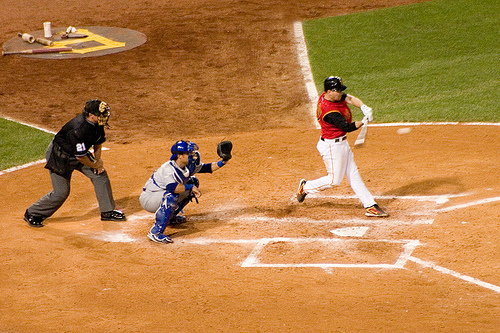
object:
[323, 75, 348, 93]
headgear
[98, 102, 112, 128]
mask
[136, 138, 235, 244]
catcher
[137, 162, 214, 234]
uniform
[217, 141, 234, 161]
mitt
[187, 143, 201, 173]
mask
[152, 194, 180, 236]
shinguards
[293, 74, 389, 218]
player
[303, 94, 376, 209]
uniform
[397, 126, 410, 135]
baseball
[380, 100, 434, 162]
air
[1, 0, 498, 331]
ground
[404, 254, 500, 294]
lines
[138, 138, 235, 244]
players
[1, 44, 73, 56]
bats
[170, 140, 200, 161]
helmet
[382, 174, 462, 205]
shadow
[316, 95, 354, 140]
red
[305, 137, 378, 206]
pants